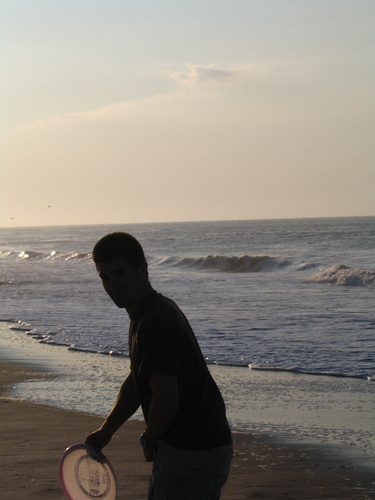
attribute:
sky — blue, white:
[3, 4, 368, 228]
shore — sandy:
[5, 312, 374, 494]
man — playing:
[70, 228, 239, 500]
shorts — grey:
[144, 440, 233, 497]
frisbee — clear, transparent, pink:
[51, 442, 117, 500]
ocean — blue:
[1, 211, 374, 375]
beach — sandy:
[3, 232, 368, 488]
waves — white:
[8, 242, 364, 380]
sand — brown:
[7, 329, 372, 494]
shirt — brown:
[116, 296, 232, 444]